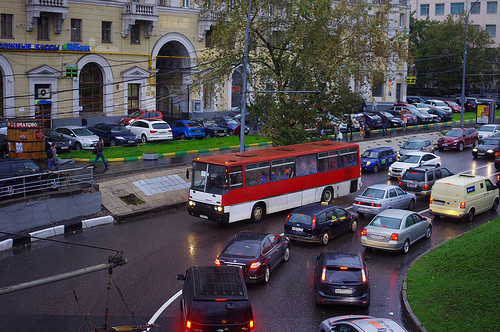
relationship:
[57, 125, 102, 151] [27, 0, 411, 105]
car near building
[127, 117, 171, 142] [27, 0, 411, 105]
car near building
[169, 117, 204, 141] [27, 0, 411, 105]
car near building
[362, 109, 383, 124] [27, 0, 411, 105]
car near building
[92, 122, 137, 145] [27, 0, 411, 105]
car near building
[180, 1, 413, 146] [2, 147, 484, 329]
tree along side of road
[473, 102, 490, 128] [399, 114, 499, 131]
sign on sidewalk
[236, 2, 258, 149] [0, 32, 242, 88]
street post connecting wire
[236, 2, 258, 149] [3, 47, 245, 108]
street post connecting wire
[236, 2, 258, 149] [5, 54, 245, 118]
street post connecting wire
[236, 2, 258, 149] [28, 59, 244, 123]
street post connecting wire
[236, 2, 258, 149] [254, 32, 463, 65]
street post connecting wire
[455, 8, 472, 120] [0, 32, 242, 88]
street post connecting wire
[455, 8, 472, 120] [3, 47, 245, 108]
street post connecting wire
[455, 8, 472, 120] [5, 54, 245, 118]
street post connecting wire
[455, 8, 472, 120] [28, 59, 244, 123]
street post connecting wire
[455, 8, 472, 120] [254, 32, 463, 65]
street post connecting wire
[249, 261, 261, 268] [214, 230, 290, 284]
light on car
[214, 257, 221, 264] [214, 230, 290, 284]
light on car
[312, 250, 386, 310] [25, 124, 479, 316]
car following road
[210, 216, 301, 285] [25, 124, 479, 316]
car following road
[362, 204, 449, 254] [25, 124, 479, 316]
car following road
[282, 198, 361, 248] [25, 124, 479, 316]
car following road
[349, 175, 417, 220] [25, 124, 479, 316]
car following road